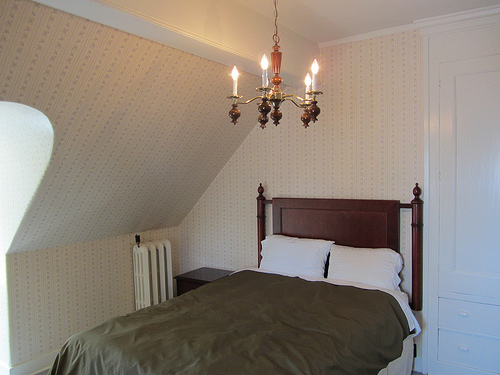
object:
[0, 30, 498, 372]
home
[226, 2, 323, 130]
chandelier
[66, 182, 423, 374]
bed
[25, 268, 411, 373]
blanket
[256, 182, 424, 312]
headboard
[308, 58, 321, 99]
lightbulbs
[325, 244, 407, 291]
pillows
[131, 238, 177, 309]
radiator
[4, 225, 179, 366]
wall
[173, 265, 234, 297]
nightstand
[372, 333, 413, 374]
bedskirt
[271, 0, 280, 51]
chain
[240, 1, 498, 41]
ceiling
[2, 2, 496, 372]
bedroom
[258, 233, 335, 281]
pillow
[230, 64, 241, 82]
lightbulb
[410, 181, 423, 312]
post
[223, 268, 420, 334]
sheet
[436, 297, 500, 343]
drawers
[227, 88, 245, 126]
holder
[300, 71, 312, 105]
lighting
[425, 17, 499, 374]
door